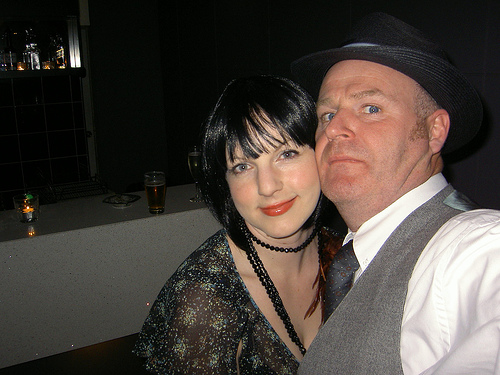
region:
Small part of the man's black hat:
[378, 24, 409, 60]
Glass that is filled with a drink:
[141, 169, 168, 212]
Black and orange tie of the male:
[331, 251, 351, 297]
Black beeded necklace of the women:
[254, 260, 290, 320]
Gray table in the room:
[61, 212, 89, 226]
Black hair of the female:
[241, 80, 277, 107]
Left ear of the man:
[423, 107, 451, 147]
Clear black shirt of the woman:
[188, 313, 219, 343]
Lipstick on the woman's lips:
[263, 202, 297, 217]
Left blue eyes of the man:
[366, 104, 382, 114]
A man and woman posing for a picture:
[132, 57, 494, 358]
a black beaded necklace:
[234, 224, 344, 372]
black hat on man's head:
[314, 30, 479, 128]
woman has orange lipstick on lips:
[256, 199, 300, 218]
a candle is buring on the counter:
[21, 186, 44, 231]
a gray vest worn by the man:
[267, 181, 499, 371]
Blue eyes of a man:
[313, 94, 390, 126]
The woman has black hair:
[183, 63, 349, 265]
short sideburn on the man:
[400, 111, 437, 146]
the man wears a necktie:
[319, 245, 376, 318]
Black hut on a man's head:
[291, 31, 498, 94]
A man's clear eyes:
[313, 104, 387, 121]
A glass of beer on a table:
[143, 171, 172, 211]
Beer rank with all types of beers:
[8, 23, 70, 71]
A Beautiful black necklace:
[238, 216, 319, 341]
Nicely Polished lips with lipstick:
[258, 191, 306, 226]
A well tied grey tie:
[309, 229, 366, 332]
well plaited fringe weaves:
[203, 56, 314, 187]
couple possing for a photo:
[190, 32, 483, 372]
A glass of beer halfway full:
[14, 191, 45, 229]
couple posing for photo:
[182, 28, 480, 356]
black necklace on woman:
[247, 241, 303, 320]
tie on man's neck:
[333, 234, 368, 279]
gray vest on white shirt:
[352, 221, 447, 348]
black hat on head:
[354, 18, 481, 99]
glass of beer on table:
[140, 164, 178, 222]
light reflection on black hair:
[202, 113, 238, 148]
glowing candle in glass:
[16, 181, 58, 229]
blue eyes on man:
[319, 96, 386, 129]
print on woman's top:
[175, 275, 227, 351]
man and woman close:
[179, 39, 498, 264]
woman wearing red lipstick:
[182, 36, 329, 305]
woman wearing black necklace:
[186, 68, 322, 343]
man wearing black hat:
[305, 19, 482, 216]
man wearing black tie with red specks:
[297, 44, 433, 334]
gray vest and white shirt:
[339, 214, 498, 364]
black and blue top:
[179, 77, 326, 374]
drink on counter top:
[122, 161, 209, 251]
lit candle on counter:
[9, 169, 79, 260]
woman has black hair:
[176, 77, 361, 299]